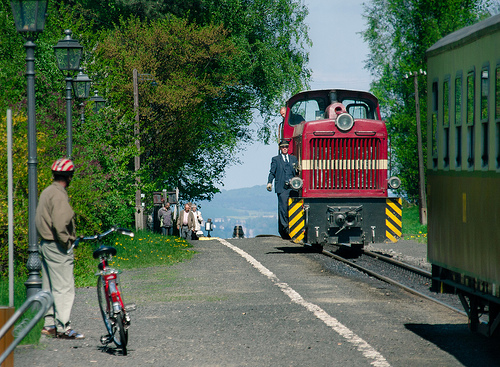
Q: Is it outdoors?
A: Yes, it is outdoors.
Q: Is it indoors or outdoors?
A: It is outdoors.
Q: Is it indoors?
A: No, it is outdoors.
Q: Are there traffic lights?
A: No, there are no traffic lights.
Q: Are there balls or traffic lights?
A: No, there are no traffic lights or balls.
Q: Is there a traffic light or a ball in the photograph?
A: No, there are no traffic lights or balls.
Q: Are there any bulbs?
A: No, there are no bulbs.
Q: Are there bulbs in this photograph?
A: No, there are no bulbs.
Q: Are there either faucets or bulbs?
A: No, there are no bulbs or faucets.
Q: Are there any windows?
A: Yes, there is a window.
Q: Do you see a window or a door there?
A: Yes, there is a window.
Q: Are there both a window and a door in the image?
A: No, there is a window but no doors.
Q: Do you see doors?
A: No, there are no doors.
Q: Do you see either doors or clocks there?
A: No, there are no doors or clocks.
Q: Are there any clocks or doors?
A: No, there are no doors or clocks.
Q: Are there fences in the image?
A: No, there are no fences.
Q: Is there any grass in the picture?
A: Yes, there is grass.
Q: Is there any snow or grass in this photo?
A: Yes, there is grass.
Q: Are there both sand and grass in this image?
A: No, there is grass but no sand.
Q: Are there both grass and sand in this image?
A: No, there is grass but no sand.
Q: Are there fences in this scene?
A: No, there are no fences.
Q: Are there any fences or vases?
A: No, there are no fences or vases.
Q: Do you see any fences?
A: No, there are no fences.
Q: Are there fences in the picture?
A: No, there are no fences.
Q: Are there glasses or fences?
A: No, there are no fences or glasses.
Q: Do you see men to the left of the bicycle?
A: Yes, there is a man to the left of the bicycle.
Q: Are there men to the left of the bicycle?
A: Yes, there is a man to the left of the bicycle.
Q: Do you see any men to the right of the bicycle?
A: No, the man is to the left of the bicycle.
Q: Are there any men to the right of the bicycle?
A: No, the man is to the left of the bicycle.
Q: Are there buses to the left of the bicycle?
A: No, there is a man to the left of the bicycle.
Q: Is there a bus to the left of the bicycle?
A: No, there is a man to the left of the bicycle.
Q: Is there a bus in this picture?
A: No, there are no buses.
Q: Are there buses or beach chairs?
A: No, there are no buses or beach chairs.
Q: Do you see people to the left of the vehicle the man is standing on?
A: Yes, there are people to the left of the train.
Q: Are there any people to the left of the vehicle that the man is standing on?
A: Yes, there are people to the left of the train.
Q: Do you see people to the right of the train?
A: No, the people are to the left of the train.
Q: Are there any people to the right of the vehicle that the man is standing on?
A: No, the people are to the left of the train.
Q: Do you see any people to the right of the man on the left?
A: Yes, there are people to the right of the man.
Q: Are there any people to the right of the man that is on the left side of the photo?
A: Yes, there are people to the right of the man.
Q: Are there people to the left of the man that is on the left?
A: No, the people are to the right of the man.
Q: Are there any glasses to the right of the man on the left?
A: No, there are people to the right of the man.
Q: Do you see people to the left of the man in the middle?
A: Yes, there are people to the left of the man.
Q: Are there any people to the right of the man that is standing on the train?
A: No, the people are to the left of the man.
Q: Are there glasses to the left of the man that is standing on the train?
A: No, there are people to the left of the man.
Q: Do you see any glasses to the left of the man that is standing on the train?
A: No, there are people to the left of the man.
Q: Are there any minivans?
A: No, there are no minivans.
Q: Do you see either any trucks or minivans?
A: No, there are no minivans or trucks.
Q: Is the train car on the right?
A: Yes, the train car is on the right of the image.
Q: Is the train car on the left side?
A: No, the train car is on the right of the image.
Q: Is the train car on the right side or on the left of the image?
A: The train car is on the right of the image.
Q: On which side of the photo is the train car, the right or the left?
A: The train car is on the right of the image.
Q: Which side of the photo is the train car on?
A: The train car is on the right of the image.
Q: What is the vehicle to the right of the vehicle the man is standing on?
A: The vehicle is a train car.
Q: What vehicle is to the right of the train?
A: The vehicle is a train car.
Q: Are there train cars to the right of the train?
A: Yes, there is a train car to the right of the train.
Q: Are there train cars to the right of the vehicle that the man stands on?
A: Yes, there is a train car to the right of the train.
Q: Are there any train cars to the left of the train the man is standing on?
A: No, the train car is to the right of the train.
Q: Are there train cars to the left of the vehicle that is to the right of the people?
A: No, the train car is to the right of the train.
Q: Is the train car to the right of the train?
A: Yes, the train car is to the right of the train.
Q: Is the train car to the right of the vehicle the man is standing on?
A: Yes, the train car is to the right of the train.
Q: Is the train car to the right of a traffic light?
A: No, the train car is to the right of the train.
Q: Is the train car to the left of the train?
A: No, the train car is to the right of the train.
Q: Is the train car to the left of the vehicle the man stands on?
A: No, the train car is to the right of the train.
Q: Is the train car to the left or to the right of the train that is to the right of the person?
A: The train car is to the right of the train.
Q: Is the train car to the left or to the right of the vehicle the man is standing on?
A: The train car is to the right of the train.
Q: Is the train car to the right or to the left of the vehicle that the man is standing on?
A: The train car is to the right of the train.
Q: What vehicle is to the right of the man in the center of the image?
A: The vehicle is a train car.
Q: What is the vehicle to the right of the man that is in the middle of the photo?
A: The vehicle is a train car.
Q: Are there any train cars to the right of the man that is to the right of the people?
A: Yes, there is a train car to the right of the man.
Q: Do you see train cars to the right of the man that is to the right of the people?
A: Yes, there is a train car to the right of the man.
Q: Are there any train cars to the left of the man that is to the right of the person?
A: No, the train car is to the right of the man.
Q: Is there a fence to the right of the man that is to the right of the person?
A: No, there is a train car to the right of the man.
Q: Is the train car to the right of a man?
A: Yes, the train car is to the right of a man.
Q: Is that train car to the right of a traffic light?
A: No, the train car is to the right of a man.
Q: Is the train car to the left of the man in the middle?
A: No, the train car is to the right of the man.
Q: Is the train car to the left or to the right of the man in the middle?
A: The train car is to the right of the man.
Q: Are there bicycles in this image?
A: Yes, there is a bicycle.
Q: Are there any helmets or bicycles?
A: Yes, there is a bicycle.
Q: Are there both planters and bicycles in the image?
A: No, there is a bicycle but no planters.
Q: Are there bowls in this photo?
A: No, there are no bowls.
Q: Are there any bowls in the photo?
A: No, there are no bowls.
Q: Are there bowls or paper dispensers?
A: No, there are no bowls or paper dispensers.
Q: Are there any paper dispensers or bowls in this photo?
A: No, there are no bowls or paper dispensers.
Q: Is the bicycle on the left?
A: Yes, the bicycle is on the left of the image.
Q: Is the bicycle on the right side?
A: No, the bicycle is on the left of the image.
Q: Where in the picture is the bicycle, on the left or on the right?
A: The bicycle is on the left of the image.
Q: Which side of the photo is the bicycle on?
A: The bicycle is on the left of the image.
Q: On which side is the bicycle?
A: The bicycle is on the left of the image.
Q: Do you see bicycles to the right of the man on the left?
A: Yes, there is a bicycle to the right of the man.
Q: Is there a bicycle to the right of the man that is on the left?
A: Yes, there is a bicycle to the right of the man.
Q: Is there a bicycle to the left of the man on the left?
A: No, the bicycle is to the right of the man.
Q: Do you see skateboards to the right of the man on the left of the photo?
A: No, there is a bicycle to the right of the man.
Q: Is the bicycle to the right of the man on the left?
A: Yes, the bicycle is to the right of the man.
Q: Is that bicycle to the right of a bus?
A: No, the bicycle is to the right of the man.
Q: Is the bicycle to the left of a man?
A: No, the bicycle is to the right of a man.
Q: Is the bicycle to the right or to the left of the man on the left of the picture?
A: The bicycle is to the right of the man.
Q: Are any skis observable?
A: No, there are no skis.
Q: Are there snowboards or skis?
A: No, there are no skis or snowboards.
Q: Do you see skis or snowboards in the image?
A: No, there are no skis or snowboards.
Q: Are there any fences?
A: No, there are no fences.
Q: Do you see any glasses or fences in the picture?
A: No, there are no fences or glasses.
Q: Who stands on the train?
A: The man stands on the train.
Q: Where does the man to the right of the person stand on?
A: The man stands on the train.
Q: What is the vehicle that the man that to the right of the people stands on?
A: The vehicle is a train.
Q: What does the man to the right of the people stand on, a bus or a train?
A: The man stands on a train.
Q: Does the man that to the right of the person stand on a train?
A: Yes, the man stands on a train.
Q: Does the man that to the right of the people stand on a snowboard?
A: No, the man stands on a train.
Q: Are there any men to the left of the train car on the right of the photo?
A: Yes, there is a man to the left of the train car.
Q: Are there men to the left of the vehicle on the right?
A: Yes, there is a man to the left of the train car.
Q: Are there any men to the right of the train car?
A: No, the man is to the left of the train car.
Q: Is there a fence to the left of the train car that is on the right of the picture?
A: No, there is a man to the left of the train car.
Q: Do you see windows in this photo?
A: Yes, there is a window.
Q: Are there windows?
A: Yes, there is a window.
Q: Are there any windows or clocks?
A: Yes, there is a window.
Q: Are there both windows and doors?
A: No, there is a window but no doors.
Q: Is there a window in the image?
A: Yes, there is a window.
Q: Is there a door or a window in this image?
A: Yes, there is a window.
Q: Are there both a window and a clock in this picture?
A: No, there is a window but no clocks.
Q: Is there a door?
A: No, there are no doors.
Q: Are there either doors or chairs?
A: No, there are no doors or chairs.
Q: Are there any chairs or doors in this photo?
A: No, there are no doors or chairs.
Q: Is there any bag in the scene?
A: No, there are no bags.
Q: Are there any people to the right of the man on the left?
A: Yes, there is a person to the right of the man.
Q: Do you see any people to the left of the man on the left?
A: No, the person is to the right of the man.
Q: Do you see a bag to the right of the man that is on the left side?
A: No, there is a person to the right of the man.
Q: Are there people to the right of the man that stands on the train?
A: No, the person is to the left of the man.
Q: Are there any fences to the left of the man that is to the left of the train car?
A: No, there is a person to the left of the man.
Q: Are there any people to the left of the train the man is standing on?
A: Yes, there is a person to the left of the train.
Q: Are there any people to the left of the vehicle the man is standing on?
A: Yes, there is a person to the left of the train.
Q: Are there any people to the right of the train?
A: No, the person is to the left of the train.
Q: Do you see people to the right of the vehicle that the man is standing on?
A: No, the person is to the left of the train.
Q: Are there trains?
A: Yes, there is a train.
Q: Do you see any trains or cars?
A: Yes, there is a train.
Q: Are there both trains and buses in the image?
A: No, there is a train but no buses.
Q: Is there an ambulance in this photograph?
A: No, there are no ambulances.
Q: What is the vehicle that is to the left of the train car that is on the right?
A: The vehicle is a train.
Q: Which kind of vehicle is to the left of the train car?
A: The vehicle is a train.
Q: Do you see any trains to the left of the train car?
A: Yes, there is a train to the left of the train car.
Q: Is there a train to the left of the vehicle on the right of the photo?
A: Yes, there is a train to the left of the train car.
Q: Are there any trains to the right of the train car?
A: No, the train is to the left of the train car.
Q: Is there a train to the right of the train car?
A: No, the train is to the left of the train car.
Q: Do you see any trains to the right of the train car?
A: No, the train is to the left of the train car.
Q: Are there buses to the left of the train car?
A: No, there is a train to the left of the train car.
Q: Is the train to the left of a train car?
A: Yes, the train is to the left of a train car.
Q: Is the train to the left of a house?
A: No, the train is to the left of a train car.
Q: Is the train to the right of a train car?
A: No, the train is to the left of a train car.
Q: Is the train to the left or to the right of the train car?
A: The train is to the left of the train car.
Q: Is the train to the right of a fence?
A: No, the train is to the right of a person.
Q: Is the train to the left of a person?
A: No, the train is to the right of a person.